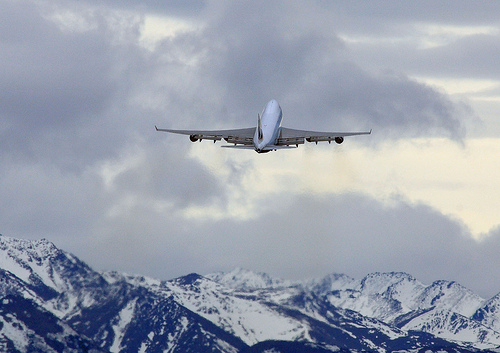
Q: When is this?
A: Daytime.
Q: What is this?
A: Plane.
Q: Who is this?
A: No one.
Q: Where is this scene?
A: Over snowy mountains.